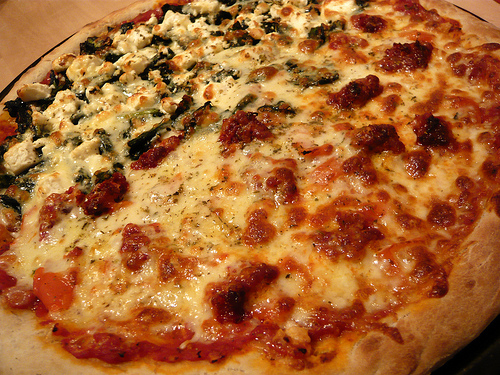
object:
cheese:
[0, 0, 500, 375]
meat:
[210, 107, 274, 159]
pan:
[0, 0, 500, 375]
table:
[0, 0, 500, 375]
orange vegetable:
[29, 266, 76, 317]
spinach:
[1, 96, 36, 137]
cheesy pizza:
[0, 0, 500, 375]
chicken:
[15, 81, 56, 103]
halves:
[0, 0, 500, 375]